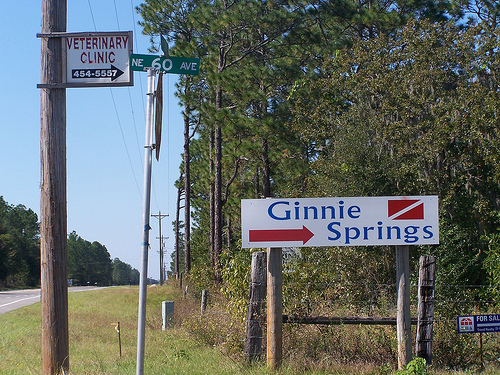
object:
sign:
[238, 196, 441, 246]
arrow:
[248, 224, 314, 245]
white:
[242, 195, 438, 245]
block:
[387, 199, 424, 220]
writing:
[267, 200, 360, 220]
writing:
[327, 222, 433, 245]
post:
[414, 255, 436, 365]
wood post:
[246, 251, 268, 361]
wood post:
[266, 248, 282, 368]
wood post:
[395, 245, 411, 370]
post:
[133, 66, 166, 374]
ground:
[0, 286, 496, 374]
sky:
[0, 0, 199, 280]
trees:
[66, 230, 85, 286]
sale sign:
[458, 315, 500, 333]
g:
[267, 201, 291, 222]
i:
[294, 201, 300, 219]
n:
[304, 206, 318, 220]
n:
[321, 205, 335, 219]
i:
[338, 200, 344, 218]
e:
[348, 206, 361, 219]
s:
[327, 222, 340, 241]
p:
[344, 227, 360, 244]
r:
[362, 227, 374, 241]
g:
[404, 226, 419, 243]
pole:
[41, 0, 66, 374]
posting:
[63, 31, 135, 84]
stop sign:
[144, 66, 173, 161]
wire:
[85, 0, 171, 204]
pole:
[415, 253, 435, 367]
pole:
[245, 251, 268, 361]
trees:
[1, 203, 43, 288]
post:
[242, 195, 441, 248]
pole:
[158, 211, 163, 285]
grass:
[1, 271, 253, 371]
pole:
[480, 333, 483, 372]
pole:
[266, 247, 282, 372]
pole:
[396, 246, 411, 368]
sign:
[66, 30, 134, 86]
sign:
[154, 73, 164, 162]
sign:
[130, 53, 201, 75]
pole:
[135, 70, 157, 375]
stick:
[117, 322, 125, 363]